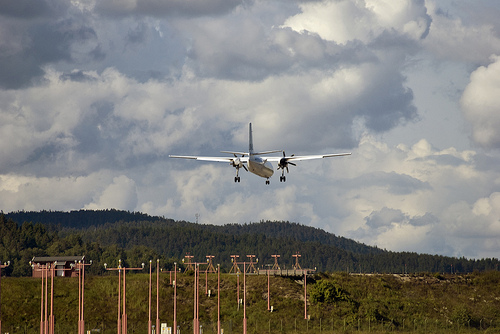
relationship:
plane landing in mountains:
[164, 121, 350, 186] [2, 200, 467, 271]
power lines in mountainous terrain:
[32, 246, 310, 332] [2, 205, 472, 332]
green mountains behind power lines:
[6, 201, 450, 271] [32, 253, 310, 330]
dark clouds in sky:
[0, 0, 443, 242] [2, 2, 482, 218]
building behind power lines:
[28, 254, 90, 277] [27, 250, 186, 331]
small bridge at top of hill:
[261, 266, 314, 278] [228, 272, 369, 331]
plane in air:
[164, 121, 350, 186] [21, 9, 480, 204]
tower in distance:
[190, 208, 203, 227] [2, 201, 484, 254]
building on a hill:
[28, 250, 92, 274] [15, 277, 114, 332]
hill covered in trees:
[0, 220, 499, 277] [270, 219, 297, 236]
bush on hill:
[306, 277, 354, 304] [3, 268, 496, 329]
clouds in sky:
[273, 5, 493, 242] [1, 0, 495, 260]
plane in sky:
[164, 121, 350, 186] [1, 0, 495, 260]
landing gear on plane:
[230, 171, 287, 182] [164, 121, 350, 186]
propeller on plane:
[273, 150, 295, 175] [164, 121, 350, 186]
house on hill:
[32, 253, 92, 276] [3, 268, 496, 329]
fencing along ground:
[243, 313, 496, 330] [1, 273, 495, 330]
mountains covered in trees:
[0, 210, 492, 273] [119, 223, 158, 243]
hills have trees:
[0, 267, 499, 330] [312, 280, 404, 315]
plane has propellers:
[164, 121, 350, 186] [273, 150, 302, 176]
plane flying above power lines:
[164, 119, 350, 186] [32, 253, 310, 330]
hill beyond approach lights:
[26, 186, 411, 269] [14, 250, 359, 331]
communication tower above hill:
[186, 205, 215, 225] [18, 188, 466, 287]